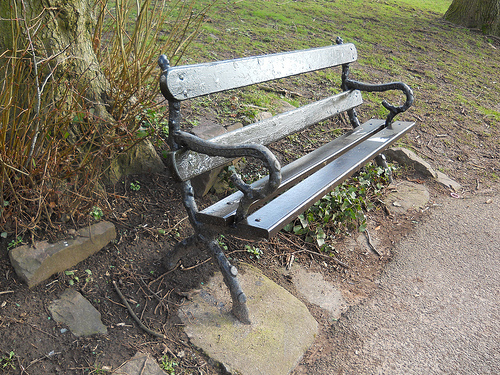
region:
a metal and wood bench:
[129, 28, 434, 329]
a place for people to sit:
[137, 30, 425, 338]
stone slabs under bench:
[171, 174, 436, 374]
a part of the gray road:
[285, 179, 499, 368]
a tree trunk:
[437, 0, 499, 50]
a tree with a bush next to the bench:
[0, 0, 195, 245]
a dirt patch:
[0, 131, 432, 369]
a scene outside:
[6, 5, 498, 372]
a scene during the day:
[4, 3, 495, 373]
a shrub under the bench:
[282, 150, 417, 240]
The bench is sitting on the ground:
[133, 30, 430, 327]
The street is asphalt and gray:
[410, 233, 499, 370]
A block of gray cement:
[166, 256, 302, 370]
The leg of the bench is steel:
[159, 213, 254, 325]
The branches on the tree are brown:
[8, 14, 100, 229]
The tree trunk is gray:
[6, 5, 169, 205]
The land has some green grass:
[218, 7, 474, 123]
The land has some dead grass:
[226, 11, 488, 149]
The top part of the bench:
[158, 41, 399, 108]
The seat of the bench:
[201, 114, 425, 251]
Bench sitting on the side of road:
[117, 24, 417, 306]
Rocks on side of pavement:
[185, 264, 316, 367]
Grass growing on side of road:
[22, 53, 162, 175]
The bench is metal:
[179, 75, 356, 263]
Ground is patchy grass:
[412, 65, 487, 121]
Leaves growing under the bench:
[292, 203, 385, 235]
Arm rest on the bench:
[152, 91, 300, 221]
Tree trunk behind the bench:
[37, 68, 184, 198]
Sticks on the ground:
[97, 256, 185, 351]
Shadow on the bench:
[315, 124, 443, 234]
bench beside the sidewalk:
[147, 27, 462, 319]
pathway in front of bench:
[307, 207, 498, 374]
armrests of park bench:
[185, 78, 433, 218]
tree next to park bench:
[17, 5, 179, 222]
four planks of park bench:
[172, 45, 439, 217]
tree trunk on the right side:
[445, 0, 495, 38]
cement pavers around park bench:
[22, 178, 497, 373]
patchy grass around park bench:
[125, 4, 490, 163]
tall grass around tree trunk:
[0, 10, 212, 206]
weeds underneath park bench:
[260, 150, 404, 254]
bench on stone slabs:
[145, 26, 437, 323]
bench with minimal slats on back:
[137, 30, 434, 328]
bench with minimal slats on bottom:
[137, 30, 434, 326]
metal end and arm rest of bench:
[142, 52, 284, 323]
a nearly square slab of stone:
[179, 257, 324, 374]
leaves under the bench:
[289, 146, 398, 261]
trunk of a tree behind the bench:
[2, 0, 169, 163]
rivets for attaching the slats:
[169, 63, 196, 105]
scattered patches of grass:
[232, 0, 441, 63]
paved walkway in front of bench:
[302, 135, 498, 374]